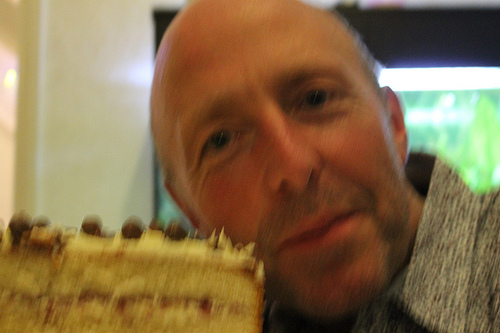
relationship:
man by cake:
[135, 5, 498, 330] [2, 209, 269, 330]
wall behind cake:
[41, 2, 142, 203] [2, 209, 269, 330]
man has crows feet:
[150, 0, 500, 333] [179, 53, 353, 174]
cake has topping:
[2, 209, 269, 330] [2, 207, 234, 254]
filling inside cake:
[6, 285, 253, 317] [2, 209, 269, 330]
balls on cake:
[72, 199, 211, 252] [7, 237, 183, 328]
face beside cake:
[170, 23, 399, 314] [16, 210, 276, 316]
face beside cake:
[170, 23, 399, 314] [29, 215, 274, 331]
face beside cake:
[170, 23, 399, 314] [46, 218, 288, 323]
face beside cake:
[170, 23, 399, 314] [49, 213, 308, 323]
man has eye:
[150, 0, 500, 333] [203, 110, 242, 185]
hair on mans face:
[254, 193, 434, 297] [169, 38, 385, 258]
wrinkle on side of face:
[175, 145, 235, 190] [170, 23, 399, 314]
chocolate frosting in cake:
[23, 276, 235, 326] [12, 196, 307, 315]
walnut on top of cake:
[7, 210, 39, 242] [2, 209, 269, 330]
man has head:
[150, 0, 500, 333] [145, 9, 415, 303]